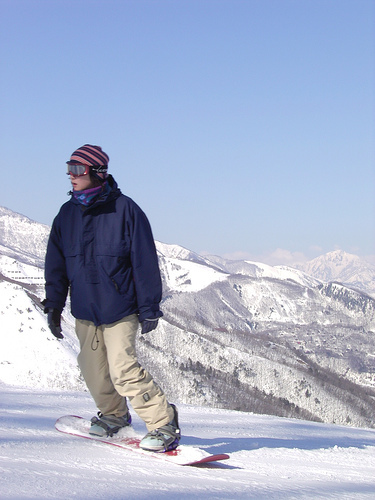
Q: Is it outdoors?
A: Yes, it is outdoors.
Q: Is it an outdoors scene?
A: Yes, it is outdoors.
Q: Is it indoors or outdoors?
A: It is outdoors.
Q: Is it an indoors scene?
A: No, it is outdoors.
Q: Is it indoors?
A: No, it is outdoors.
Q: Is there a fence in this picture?
A: No, there are no fences.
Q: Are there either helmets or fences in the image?
A: No, there are no fences or helmets.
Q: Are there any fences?
A: No, there are no fences.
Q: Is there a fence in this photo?
A: No, there are no fences.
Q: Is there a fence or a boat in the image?
A: No, there are no fences or boats.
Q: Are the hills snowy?
A: Yes, the hills are snowy.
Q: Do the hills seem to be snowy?
A: Yes, the hills are snowy.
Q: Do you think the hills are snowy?
A: Yes, the hills are snowy.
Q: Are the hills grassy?
A: No, the hills are snowy.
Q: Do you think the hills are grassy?
A: No, the hills are snowy.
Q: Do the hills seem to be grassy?
A: No, the hills are snowy.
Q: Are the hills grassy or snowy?
A: The hills are snowy.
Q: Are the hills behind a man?
A: Yes, the hills are behind a man.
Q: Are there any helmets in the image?
A: No, there are no helmets.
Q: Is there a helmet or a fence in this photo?
A: No, there are no helmets or fences.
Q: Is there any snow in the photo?
A: Yes, there is snow.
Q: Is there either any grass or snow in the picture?
A: Yes, there is snow.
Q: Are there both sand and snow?
A: No, there is snow but no sand.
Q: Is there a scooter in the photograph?
A: No, there are no scooters.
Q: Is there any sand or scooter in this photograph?
A: No, there are no scooters or sand.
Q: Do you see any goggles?
A: Yes, there are goggles.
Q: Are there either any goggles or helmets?
A: Yes, there are goggles.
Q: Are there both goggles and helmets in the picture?
A: No, there are goggles but no helmets.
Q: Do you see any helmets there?
A: No, there are no helmets.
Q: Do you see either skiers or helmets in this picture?
A: No, there are no helmets or skiers.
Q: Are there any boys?
A: No, there are no boys.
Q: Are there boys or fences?
A: No, there are no boys or fences.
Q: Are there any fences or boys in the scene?
A: No, there are no boys or fences.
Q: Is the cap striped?
A: Yes, the cap is striped.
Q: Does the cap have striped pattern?
A: Yes, the cap is striped.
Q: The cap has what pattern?
A: The cap is striped.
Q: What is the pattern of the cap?
A: The cap is striped.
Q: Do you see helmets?
A: No, there are no helmets.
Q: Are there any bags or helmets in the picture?
A: No, there are no helmets or bags.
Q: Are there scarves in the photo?
A: Yes, there is a scarf.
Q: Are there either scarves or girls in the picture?
A: Yes, there is a scarf.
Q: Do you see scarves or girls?
A: Yes, there is a scarf.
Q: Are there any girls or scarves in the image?
A: Yes, there is a scarf.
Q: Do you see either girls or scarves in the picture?
A: Yes, there is a scarf.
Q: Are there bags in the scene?
A: No, there are no bags.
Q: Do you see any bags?
A: No, there are no bags.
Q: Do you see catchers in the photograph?
A: No, there are no catchers.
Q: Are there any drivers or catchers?
A: No, there are no catchers or drivers.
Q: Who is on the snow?
A: The man is on the snow.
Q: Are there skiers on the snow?
A: No, there is a man on the snow.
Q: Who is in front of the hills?
A: The man is in front of the hills.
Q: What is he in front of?
A: The man is in front of the hills.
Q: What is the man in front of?
A: The man is in front of the hills.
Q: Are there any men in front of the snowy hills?
A: Yes, there is a man in front of the hills.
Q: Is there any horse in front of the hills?
A: No, there is a man in front of the hills.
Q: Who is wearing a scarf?
A: The man is wearing a scarf.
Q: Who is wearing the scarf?
A: The man is wearing a scarf.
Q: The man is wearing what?
A: The man is wearing a scarf.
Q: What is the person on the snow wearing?
A: The man is wearing a scarf.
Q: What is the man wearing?
A: The man is wearing a scarf.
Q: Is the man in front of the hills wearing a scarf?
A: Yes, the man is wearing a scarf.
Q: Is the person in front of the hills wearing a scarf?
A: Yes, the man is wearing a scarf.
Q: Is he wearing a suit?
A: No, the man is wearing a scarf.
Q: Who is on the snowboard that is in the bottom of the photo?
A: The man is on the snowboard.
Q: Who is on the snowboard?
A: The man is on the snowboard.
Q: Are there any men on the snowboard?
A: Yes, there is a man on the snowboard.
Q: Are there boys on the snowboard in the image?
A: No, there is a man on the snowboard.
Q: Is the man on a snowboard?
A: Yes, the man is on a snowboard.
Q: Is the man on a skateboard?
A: No, the man is on a snowboard.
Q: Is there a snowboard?
A: Yes, there is a snowboard.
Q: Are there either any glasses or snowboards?
A: Yes, there is a snowboard.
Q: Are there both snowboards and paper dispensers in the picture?
A: No, there is a snowboard but no paper dispensers.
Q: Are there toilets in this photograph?
A: No, there are no toilets.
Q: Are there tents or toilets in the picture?
A: No, there are no toilets or tents.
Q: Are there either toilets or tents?
A: No, there are no toilets or tents.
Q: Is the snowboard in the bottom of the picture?
A: Yes, the snowboard is in the bottom of the image.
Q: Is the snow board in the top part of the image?
A: No, the snow board is in the bottom of the image.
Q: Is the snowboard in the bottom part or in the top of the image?
A: The snowboard is in the bottom of the image.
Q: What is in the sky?
A: The clouds are in the sky.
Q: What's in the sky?
A: The clouds are in the sky.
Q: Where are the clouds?
A: The clouds are in the sky.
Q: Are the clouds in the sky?
A: Yes, the clouds are in the sky.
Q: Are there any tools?
A: No, there are no tools.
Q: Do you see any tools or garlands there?
A: No, there are no tools or garlands.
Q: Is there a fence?
A: No, there are no fences.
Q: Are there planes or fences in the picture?
A: No, there are no fences or planes.